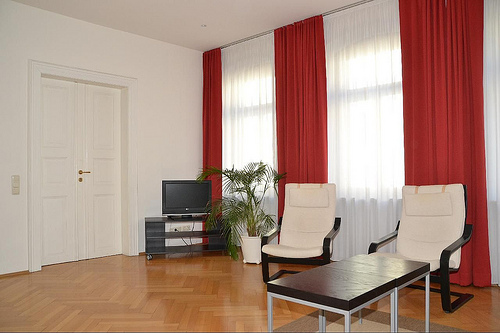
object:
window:
[219, 0, 499, 201]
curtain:
[201, 49, 226, 245]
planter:
[238, 235, 263, 265]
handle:
[78, 171, 94, 176]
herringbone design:
[1, 247, 499, 332]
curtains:
[219, 0, 499, 285]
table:
[264, 253, 430, 333]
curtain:
[397, 1, 493, 289]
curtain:
[273, 17, 329, 219]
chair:
[366, 183, 476, 314]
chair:
[260, 183, 341, 284]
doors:
[41, 75, 81, 266]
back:
[394, 184, 467, 270]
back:
[279, 183, 336, 248]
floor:
[0, 243, 500, 331]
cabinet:
[145, 216, 234, 255]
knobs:
[77, 176, 85, 184]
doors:
[78, 86, 121, 262]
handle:
[437, 224, 476, 276]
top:
[283, 182, 335, 195]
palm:
[194, 153, 286, 261]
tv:
[158, 177, 213, 220]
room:
[0, 1, 499, 333]